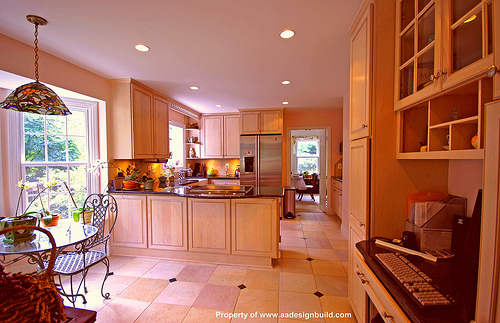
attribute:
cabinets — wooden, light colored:
[389, 5, 498, 165]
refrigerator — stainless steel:
[240, 137, 282, 197]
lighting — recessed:
[133, 42, 150, 53]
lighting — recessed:
[279, 27, 294, 42]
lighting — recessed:
[281, 79, 291, 88]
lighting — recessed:
[189, 84, 199, 92]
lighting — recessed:
[280, 99, 290, 106]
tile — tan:
[200, 251, 322, 311]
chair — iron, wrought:
[35, 192, 120, 302]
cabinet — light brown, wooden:
[109, 191, 279, 268]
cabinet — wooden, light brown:
[112, 79, 169, 159]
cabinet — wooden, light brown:
[200, 113, 240, 157]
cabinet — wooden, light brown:
[240, 108, 282, 133]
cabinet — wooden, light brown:
[347, 1, 372, 141]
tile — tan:
[280, 272, 317, 292]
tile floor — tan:
[49, 206, 346, 320]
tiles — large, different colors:
[51, 254, 357, 321]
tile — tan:
[174, 256, 266, 316]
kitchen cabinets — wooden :
[105, 193, 282, 268]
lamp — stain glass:
[6, 10, 92, 124]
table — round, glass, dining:
[7, 218, 99, 321]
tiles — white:
[56, 242, 355, 319]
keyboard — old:
[378, 257, 498, 314]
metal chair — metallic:
[37, 192, 117, 299]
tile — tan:
[271, 267, 318, 295]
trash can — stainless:
[284, 186, 297, 220]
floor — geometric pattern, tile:
[295, 217, 350, 314]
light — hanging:
[18, 78, 86, 112]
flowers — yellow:
[12, 177, 58, 234]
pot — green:
[40, 213, 60, 225]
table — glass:
[1, 214, 94, 260]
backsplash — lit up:
[196, 153, 244, 179]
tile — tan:
[281, 246, 309, 266]